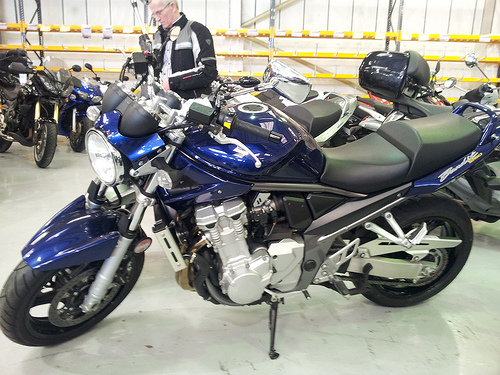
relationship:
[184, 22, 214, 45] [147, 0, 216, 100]
shoulder on man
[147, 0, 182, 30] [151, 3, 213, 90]
head belonging to man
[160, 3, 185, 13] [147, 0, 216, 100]
ear belonging to man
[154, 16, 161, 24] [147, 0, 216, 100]
man's nose belonging to man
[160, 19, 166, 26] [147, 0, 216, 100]
mouth belonging to man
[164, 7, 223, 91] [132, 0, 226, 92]
arm belonging to man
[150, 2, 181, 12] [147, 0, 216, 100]
hair belonging to man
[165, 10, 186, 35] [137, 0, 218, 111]
neck belonging to man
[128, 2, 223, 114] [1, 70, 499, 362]
man standing near bike